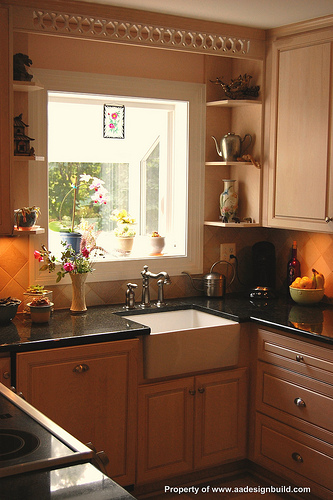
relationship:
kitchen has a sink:
[0, 2, 332, 498] [122, 304, 241, 382]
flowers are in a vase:
[33, 240, 105, 279] [68, 271, 92, 312]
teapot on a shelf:
[210, 133, 251, 161] [207, 161, 257, 168]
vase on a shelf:
[221, 180, 240, 221] [205, 218, 255, 230]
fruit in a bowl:
[293, 269, 325, 290] [291, 285, 323, 305]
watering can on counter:
[195, 258, 238, 301] [0, 293, 332, 352]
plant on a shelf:
[208, 73, 262, 97] [205, 97, 260, 107]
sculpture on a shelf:
[14, 51, 36, 81] [14, 82, 44, 94]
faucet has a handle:
[123, 264, 169, 309] [128, 281, 138, 290]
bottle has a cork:
[286, 240, 300, 284] [290, 240, 298, 248]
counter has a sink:
[0, 293, 332, 352] [122, 304, 241, 382]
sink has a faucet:
[122, 304, 241, 382] [123, 264, 169, 309]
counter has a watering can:
[0, 293, 332, 352] [195, 258, 238, 301]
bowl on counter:
[291, 285, 323, 305] [0, 293, 332, 352]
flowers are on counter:
[33, 240, 105, 279] [0, 293, 332, 352]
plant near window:
[208, 73, 262, 97] [45, 92, 188, 264]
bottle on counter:
[286, 240, 300, 284] [0, 293, 332, 352]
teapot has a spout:
[210, 133, 251, 161] [212, 137, 224, 157]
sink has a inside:
[122, 304, 241, 382] [126, 309, 235, 335]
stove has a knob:
[2, 381, 93, 481] [97, 448, 109, 464]